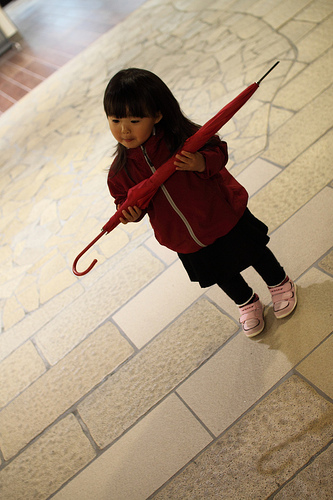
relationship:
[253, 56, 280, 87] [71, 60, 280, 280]
point on end of umbrella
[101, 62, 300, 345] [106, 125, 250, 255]
girl wearing jacket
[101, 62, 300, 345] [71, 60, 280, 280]
girl holding umbrella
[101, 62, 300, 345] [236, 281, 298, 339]
girl wearing sneakers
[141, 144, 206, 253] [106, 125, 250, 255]
zipper on hoodie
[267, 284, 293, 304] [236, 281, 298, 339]
velco straps are on sneakers